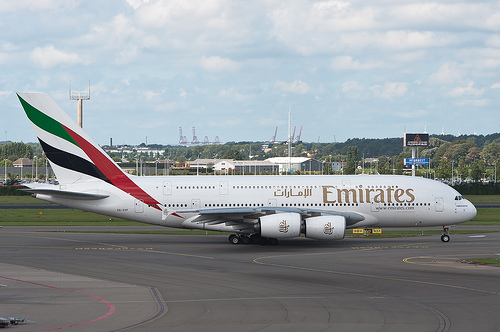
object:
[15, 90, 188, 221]
logo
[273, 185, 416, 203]
logo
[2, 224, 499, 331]
runway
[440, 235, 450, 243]
wheel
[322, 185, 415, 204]
name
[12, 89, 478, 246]
plane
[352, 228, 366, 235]
barrier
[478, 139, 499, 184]
tree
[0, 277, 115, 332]
paint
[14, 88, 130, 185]
tail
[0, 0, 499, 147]
sky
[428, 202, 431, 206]
window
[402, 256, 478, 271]
paint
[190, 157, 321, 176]
building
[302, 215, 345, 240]
engine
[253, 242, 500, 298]
line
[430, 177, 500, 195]
parking lot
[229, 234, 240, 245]
back wheel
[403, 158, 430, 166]
sign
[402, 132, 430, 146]
sign